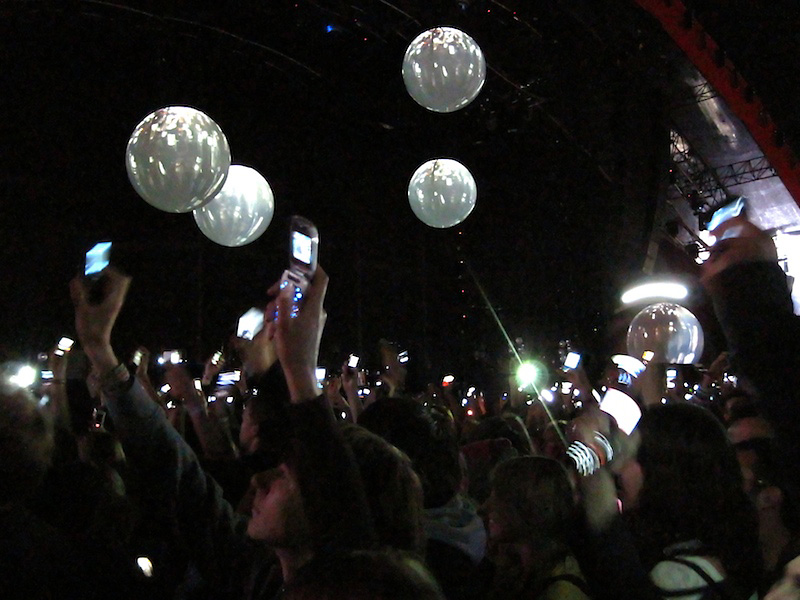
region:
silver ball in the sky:
[398, 146, 475, 229]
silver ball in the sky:
[633, 303, 692, 353]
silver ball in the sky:
[397, 25, 483, 111]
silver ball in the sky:
[122, 98, 221, 196]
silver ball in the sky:
[191, 153, 272, 238]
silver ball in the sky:
[399, 150, 487, 241]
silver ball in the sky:
[119, 96, 234, 219]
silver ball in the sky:
[618, 298, 701, 363]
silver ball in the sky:
[398, 18, 489, 116]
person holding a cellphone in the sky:
[224, 304, 266, 353]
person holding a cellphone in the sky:
[568, 382, 645, 494]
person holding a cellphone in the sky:
[338, 346, 366, 373]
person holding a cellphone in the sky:
[47, 335, 79, 376]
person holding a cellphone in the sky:
[154, 344, 190, 379]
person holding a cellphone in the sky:
[464, 374, 478, 400]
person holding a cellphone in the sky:
[310, 366, 335, 401]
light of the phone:
[236, 320, 255, 337]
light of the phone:
[82, 254, 115, 278]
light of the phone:
[282, 232, 317, 261]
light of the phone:
[339, 357, 366, 373]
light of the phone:
[60, 330, 72, 349]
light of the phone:
[133, 555, 152, 571]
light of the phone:
[558, 445, 598, 471]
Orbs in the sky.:
[82, 39, 629, 258]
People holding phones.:
[60, 190, 487, 592]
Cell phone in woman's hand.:
[205, 158, 371, 356]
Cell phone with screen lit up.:
[56, 217, 195, 390]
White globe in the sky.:
[121, 74, 521, 347]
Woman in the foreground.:
[210, 380, 546, 597]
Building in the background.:
[575, 93, 777, 269]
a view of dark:
[288, 89, 358, 161]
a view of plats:
[121, 112, 197, 192]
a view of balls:
[124, 128, 224, 206]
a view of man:
[192, 437, 411, 599]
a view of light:
[464, 336, 547, 416]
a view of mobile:
[246, 232, 355, 334]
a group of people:
[132, 232, 661, 596]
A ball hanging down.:
[404, 156, 478, 225]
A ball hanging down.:
[401, 25, 485, 108]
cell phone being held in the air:
[75, 230, 115, 288]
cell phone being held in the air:
[265, 216, 323, 322]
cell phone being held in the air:
[237, 302, 277, 362]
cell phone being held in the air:
[53, 329, 77, 357]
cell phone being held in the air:
[28, 350, 49, 394]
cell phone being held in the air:
[553, 384, 643, 480]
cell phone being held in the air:
[560, 346, 580, 375]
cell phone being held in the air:
[704, 188, 752, 245]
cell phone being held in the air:
[440, 368, 453, 395]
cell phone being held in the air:
[345, 347, 363, 379]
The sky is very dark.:
[5, 0, 794, 366]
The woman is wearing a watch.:
[81, 355, 129, 399]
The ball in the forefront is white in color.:
[118, 104, 233, 209]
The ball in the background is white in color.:
[404, 162, 474, 229]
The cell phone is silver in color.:
[273, 212, 322, 330]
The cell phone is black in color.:
[77, 238, 117, 305]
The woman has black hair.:
[619, 405, 761, 587]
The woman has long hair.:
[617, 399, 763, 591]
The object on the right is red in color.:
[640, 5, 798, 206]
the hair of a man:
[337, 429, 441, 539]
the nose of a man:
[233, 471, 277, 498]